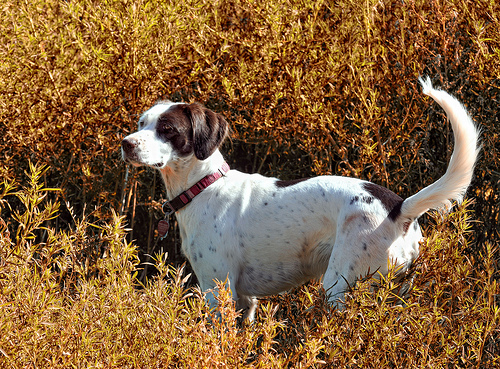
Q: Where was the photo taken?
A: It was taken at the field.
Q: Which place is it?
A: It is a field.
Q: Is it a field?
A: Yes, it is a field.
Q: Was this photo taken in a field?
A: Yes, it was taken in a field.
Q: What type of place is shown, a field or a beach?
A: It is a field.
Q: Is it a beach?
A: No, it is a field.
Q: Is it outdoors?
A: Yes, it is outdoors.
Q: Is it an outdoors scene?
A: Yes, it is outdoors.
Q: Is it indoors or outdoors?
A: It is outdoors.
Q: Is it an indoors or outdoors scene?
A: It is outdoors.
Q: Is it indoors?
A: No, it is outdoors.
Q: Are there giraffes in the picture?
A: No, there are no giraffes.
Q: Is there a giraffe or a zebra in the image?
A: No, there are no giraffes or zebras.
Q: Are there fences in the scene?
A: No, there are no fences.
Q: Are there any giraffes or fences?
A: No, there are no fences or giraffes.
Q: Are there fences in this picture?
A: No, there are no fences.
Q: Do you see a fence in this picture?
A: No, there are no fences.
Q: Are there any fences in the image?
A: No, there are no fences.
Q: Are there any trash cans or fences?
A: No, there are no fences or trash cans.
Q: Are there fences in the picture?
A: No, there are no fences.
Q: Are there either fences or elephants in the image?
A: No, there are no fences or elephants.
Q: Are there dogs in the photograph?
A: Yes, there is a dog.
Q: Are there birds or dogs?
A: Yes, there is a dog.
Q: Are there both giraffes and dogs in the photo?
A: No, there is a dog but no giraffes.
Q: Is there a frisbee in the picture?
A: No, there are no frisbees.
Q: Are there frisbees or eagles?
A: No, there are no frisbees or eagles.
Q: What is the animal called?
A: The animal is a dog.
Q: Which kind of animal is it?
A: The animal is a dog.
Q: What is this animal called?
A: This is a dog.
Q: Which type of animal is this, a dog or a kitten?
A: This is a dog.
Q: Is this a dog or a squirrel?
A: This is a dog.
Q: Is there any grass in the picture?
A: Yes, there is grass.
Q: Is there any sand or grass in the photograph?
A: Yes, there is grass.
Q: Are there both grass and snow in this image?
A: No, there is grass but no snow.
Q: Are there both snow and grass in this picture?
A: No, there is grass but no snow.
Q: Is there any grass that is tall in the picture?
A: Yes, there is tall grass.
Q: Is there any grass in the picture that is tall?
A: Yes, there is grass that is tall.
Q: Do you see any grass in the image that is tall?
A: Yes, there is grass that is tall.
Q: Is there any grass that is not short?
A: Yes, there is tall grass.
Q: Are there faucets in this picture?
A: No, there are no faucets.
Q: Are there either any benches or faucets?
A: No, there are no faucets or benches.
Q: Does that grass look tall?
A: Yes, the grass is tall.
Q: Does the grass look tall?
A: Yes, the grass is tall.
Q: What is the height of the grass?
A: The grass is tall.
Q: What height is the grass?
A: The grass is tall.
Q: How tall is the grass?
A: The grass is tall.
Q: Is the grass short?
A: No, the grass is tall.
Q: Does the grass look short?
A: No, the grass is tall.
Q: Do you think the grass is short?
A: No, the grass is tall.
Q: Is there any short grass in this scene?
A: No, there is grass but it is tall.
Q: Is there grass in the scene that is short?
A: No, there is grass but it is tall.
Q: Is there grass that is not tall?
A: No, there is grass but it is tall.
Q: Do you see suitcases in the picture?
A: No, there are no suitcases.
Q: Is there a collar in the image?
A: Yes, there is a collar.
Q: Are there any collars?
A: Yes, there is a collar.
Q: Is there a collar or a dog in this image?
A: Yes, there is a collar.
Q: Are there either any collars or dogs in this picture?
A: Yes, there is a collar.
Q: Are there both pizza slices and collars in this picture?
A: No, there is a collar but no pizza slices.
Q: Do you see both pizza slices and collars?
A: No, there is a collar but no pizza slices.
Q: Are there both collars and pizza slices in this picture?
A: No, there is a collar but no pizza slices.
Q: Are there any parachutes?
A: No, there are no parachutes.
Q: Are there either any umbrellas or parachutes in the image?
A: No, there are no parachutes or umbrellas.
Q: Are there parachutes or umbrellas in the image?
A: No, there are no parachutes or umbrellas.